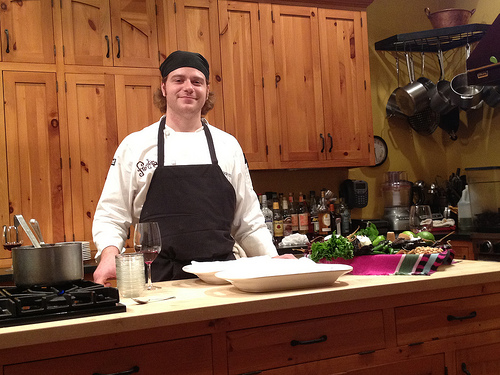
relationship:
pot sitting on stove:
[11, 219, 85, 282] [0, 276, 126, 331]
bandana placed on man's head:
[160, 50, 208, 77] [162, 51, 209, 112]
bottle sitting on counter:
[317, 190, 331, 238] [269, 231, 474, 253]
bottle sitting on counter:
[296, 190, 310, 231] [269, 231, 474, 253]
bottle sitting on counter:
[272, 194, 284, 241] [269, 231, 474, 253]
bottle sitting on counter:
[279, 196, 293, 239] [269, 231, 474, 253]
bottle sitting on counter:
[338, 198, 352, 233] [269, 231, 474, 253]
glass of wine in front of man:
[134, 218, 162, 288] [91, 48, 296, 288]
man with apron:
[91, 48, 296, 288] [139, 115, 235, 279]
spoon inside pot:
[13, 213, 41, 249] [11, 219, 85, 282]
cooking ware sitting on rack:
[424, 4, 478, 28] [374, 21, 490, 54]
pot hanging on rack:
[448, 43, 487, 109] [374, 21, 490, 54]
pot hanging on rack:
[428, 48, 460, 116] [374, 21, 490, 54]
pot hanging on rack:
[397, 48, 428, 115] [374, 21, 490, 54]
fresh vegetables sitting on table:
[303, 220, 446, 261] [0, 257, 499, 373]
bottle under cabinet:
[317, 190, 331, 238] [269, 0, 378, 167]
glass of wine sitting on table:
[134, 218, 162, 288] [0, 257, 499, 373]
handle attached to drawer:
[446, 310, 479, 323] [394, 278, 499, 347]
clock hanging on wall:
[372, 134, 387, 168] [246, 0, 499, 221]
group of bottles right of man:
[252, 187, 351, 240] [91, 48, 296, 288]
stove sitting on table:
[0, 276, 126, 331] [0, 257, 499, 373]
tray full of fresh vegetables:
[316, 249, 453, 276] [303, 220, 446, 261]